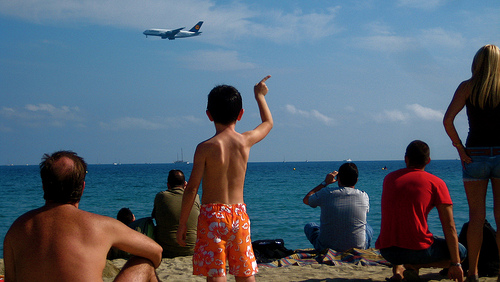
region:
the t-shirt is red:
[371, 165, 442, 252]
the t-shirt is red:
[364, 170, 445, 255]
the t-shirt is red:
[364, 165, 462, 253]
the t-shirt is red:
[375, 165, 448, 248]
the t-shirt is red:
[364, 165, 444, 244]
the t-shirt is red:
[372, 156, 442, 259]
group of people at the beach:
[3, 41, 498, 280]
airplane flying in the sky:
[3, 2, 498, 152]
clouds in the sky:
[3, 2, 499, 159]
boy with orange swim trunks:
[174, 73, 275, 280]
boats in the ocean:
[0, 140, 499, 251]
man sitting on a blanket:
[243, 159, 394, 267]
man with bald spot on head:
[0, 150, 164, 279]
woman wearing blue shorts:
[442, 45, 499, 280]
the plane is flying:
[122, 16, 217, 51]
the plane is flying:
[130, 14, 211, 59]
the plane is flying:
[134, 12, 217, 62]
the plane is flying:
[129, 9, 228, 61]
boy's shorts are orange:
[188, 196, 261, 266]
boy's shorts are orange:
[200, 198, 246, 274]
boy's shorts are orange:
[191, 205, 261, 272]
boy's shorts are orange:
[191, 203, 252, 278]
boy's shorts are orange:
[183, 185, 248, 275]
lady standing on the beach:
[416, 45, 498, 276]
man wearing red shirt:
[362, 123, 479, 280]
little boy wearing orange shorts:
[167, 65, 303, 280]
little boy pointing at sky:
[179, 65, 299, 272]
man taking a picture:
[304, 139, 373, 280]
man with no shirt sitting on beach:
[7, 128, 207, 280]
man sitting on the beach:
[112, 159, 217, 279]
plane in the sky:
[125, 10, 255, 67]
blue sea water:
[7, 163, 499, 263]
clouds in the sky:
[253, 90, 470, 145]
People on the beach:
[0, 42, 499, 278]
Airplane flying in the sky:
[142, 17, 207, 42]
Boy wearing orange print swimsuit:
[176, 73, 275, 279]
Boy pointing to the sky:
[176, 72, 276, 278]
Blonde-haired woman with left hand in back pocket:
[442, 40, 498, 276]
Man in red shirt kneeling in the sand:
[374, 136, 464, 278]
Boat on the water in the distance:
[168, 150, 194, 168]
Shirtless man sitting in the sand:
[1, 147, 164, 280]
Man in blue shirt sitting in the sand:
[302, 162, 375, 244]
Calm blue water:
[2, 157, 498, 246]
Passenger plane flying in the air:
[139, 20, 206, 41]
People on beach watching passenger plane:
[3, 19, 499, 278]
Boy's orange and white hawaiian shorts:
[191, 202, 260, 277]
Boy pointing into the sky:
[174, 66, 274, 280]